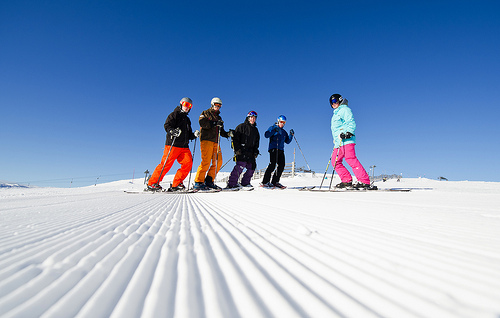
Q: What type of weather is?
A: It is clear.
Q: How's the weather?
A: It is clear.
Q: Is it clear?
A: Yes, it is clear.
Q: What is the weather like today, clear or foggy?
A: It is clear.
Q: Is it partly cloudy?
A: No, it is clear.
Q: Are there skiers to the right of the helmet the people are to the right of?
A: No, the skier is to the left of the helmet.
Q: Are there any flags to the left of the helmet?
A: No, there is a skier to the left of the helmet.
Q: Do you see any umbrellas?
A: No, there are no umbrellas.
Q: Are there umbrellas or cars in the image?
A: No, there are no umbrellas or cars.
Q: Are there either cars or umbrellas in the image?
A: No, there are no umbrellas or cars.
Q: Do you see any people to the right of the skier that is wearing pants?
A: Yes, there are people to the right of the skier.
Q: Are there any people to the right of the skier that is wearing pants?
A: Yes, there are people to the right of the skier.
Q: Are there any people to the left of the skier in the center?
A: No, the people are to the right of the skier.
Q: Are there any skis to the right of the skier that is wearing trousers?
A: No, there are people to the right of the skier.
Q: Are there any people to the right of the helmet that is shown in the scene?
A: Yes, there are people to the right of the helmet.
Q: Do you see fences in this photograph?
A: No, there are no fences.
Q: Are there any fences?
A: No, there are no fences.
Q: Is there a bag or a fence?
A: No, there are no fences or bags.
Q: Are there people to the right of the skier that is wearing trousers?
A: Yes, there is a person to the right of the skier.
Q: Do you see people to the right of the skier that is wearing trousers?
A: Yes, there is a person to the right of the skier.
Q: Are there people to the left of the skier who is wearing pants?
A: No, the person is to the right of the skier.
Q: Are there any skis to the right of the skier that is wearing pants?
A: No, there is a person to the right of the skier.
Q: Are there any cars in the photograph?
A: No, there are no cars.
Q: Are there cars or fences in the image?
A: No, there are no cars or fences.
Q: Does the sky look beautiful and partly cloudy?
A: No, the sky is beautiful but clear.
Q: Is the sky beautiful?
A: Yes, the sky is beautiful.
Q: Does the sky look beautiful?
A: Yes, the sky is beautiful.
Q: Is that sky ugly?
A: No, the sky is beautiful.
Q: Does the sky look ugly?
A: No, the sky is beautiful.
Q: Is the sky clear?
A: Yes, the sky is clear.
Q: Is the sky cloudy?
A: No, the sky is clear.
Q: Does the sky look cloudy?
A: No, the sky is clear.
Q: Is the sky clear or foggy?
A: The sky is clear.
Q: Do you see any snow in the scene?
A: Yes, there is snow.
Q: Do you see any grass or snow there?
A: Yes, there is snow.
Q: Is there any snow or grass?
A: Yes, there is snow.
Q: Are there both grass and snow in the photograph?
A: No, there is snow but no grass.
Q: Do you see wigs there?
A: No, there are no wigs.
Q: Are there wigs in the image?
A: No, there are no wigs.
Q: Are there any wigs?
A: No, there are no wigs.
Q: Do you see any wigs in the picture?
A: No, there are no wigs.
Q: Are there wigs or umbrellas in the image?
A: No, there are no wigs or umbrellas.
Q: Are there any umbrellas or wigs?
A: No, there are no wigs or umbrellas.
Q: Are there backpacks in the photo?
A: No, there are no backpacks.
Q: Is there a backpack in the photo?
A: No, there are no backpacks.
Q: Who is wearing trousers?
A: The skier is wearing trousers.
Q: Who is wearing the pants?
A: The skier is wearing trousers.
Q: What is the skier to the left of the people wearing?
A: The skier is wearing pants.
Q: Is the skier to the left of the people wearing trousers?
A: Yes, the skier is wearing trousers.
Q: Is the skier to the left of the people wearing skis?
A: No, the skier is wearing trousers.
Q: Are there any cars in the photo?
A: No, there are no cars.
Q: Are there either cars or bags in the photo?
A: No, there are no cars or bags.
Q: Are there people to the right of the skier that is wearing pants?
A: Yes, there is a person to the right of the skier.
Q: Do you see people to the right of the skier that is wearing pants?
A: Yes, there is a person to the right of the skier.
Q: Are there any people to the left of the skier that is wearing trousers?
A: No, the person is to the right of the skier.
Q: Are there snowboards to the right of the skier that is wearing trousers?
A: No, there is a person to the right of the skier.